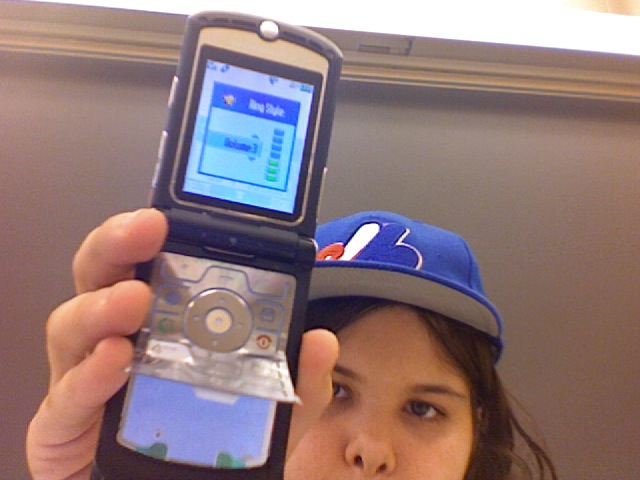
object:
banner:
[211, 80, 301, 126]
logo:
[315, 222, 423, 270]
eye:
[402, 399, 445, 419]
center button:
[206, 309, 233, 334]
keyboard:
[121, 251, 294, 402]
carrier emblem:
[259, 20, 279, 39]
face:
[283, 304, 475, 480]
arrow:
[219, 298, 225, 303]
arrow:
[237, 323, 243, 328]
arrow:
[212, 340, 218, 346]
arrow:
[192, 313, 200, 320]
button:
[256, 334, 273, 350]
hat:
[305, 210, 502, 366]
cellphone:
[88, 10, 345, 480]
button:
[158, 317, 176, 334]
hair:
[301, 295, 558, 480]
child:
[24, 208, 556, 480]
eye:
[332, 380, 350, 399]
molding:
[0, 0, 640, 103]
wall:
[0, 51, 640, 480]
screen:
[180, 59, 315, 214]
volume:
[205, 133, 263, 162]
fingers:
[24, 206, 169, 450]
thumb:
[284, 328, 340, 463]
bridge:
[344, 385, 396, 474]